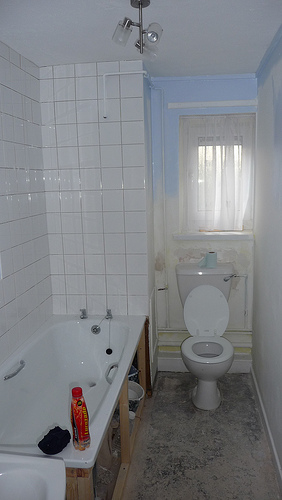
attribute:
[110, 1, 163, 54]
light — silver, metal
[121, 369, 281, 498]
floor — unfinished, bare, dirty, black, gray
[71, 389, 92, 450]
bottle — red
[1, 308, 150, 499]
tub — white, unfinished, in construction, opened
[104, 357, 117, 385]
handle — silver, metalic, metal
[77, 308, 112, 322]
faucet — silver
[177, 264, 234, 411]
toilet — open, white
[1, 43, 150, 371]
tile — white, square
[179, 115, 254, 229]
curtain — white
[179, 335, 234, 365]
seat — white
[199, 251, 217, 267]
paper — roll, small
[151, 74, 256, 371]
wall — blue, painted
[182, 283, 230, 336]
lid — up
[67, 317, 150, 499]
poles — wooden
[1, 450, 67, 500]
sink — white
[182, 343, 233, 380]
bowl — white